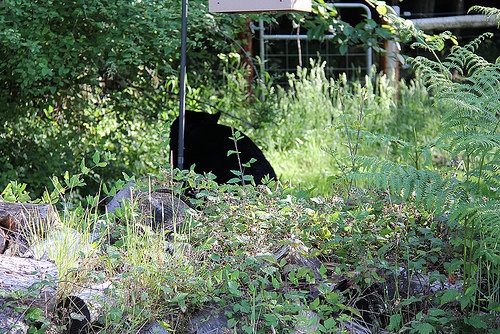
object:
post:
[382, 3, 498, 106]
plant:
[378, 34, 499, 181]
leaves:
[173, 205, 372, 317]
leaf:
[104, 96, 114, 105]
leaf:
[0, 0, 236, 218]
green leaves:
[0, 3, 235, 193]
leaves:
[273, 1, 425, 52]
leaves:
[176, 172, 424, 332]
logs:
[1, 256, 105, 309]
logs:
[1, 307, 52, 332]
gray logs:
[0, 254, 105, 321]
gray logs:
[1, 309, 59, 332]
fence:
[255, 5, 402, 89]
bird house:
[207, 0, 312, 14]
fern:
[408, 47, 498, 187]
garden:
[3, 80, 498, 330]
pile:
[0, 175, 482, 332]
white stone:
[98, 186, 196, 239]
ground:
[13, 190, 495, 329]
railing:
[372, 10, 499, 32]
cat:
[168, 109, 279, 186]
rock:
[265, 267, 309, 314]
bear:
[168, 110, 278, 187]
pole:
[178, 0, 188, 174]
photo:
[0, 0, 498, 334]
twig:
[265, 52, 420, 180]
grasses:
[299, 118, 407, 200]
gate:
[269, 33, 361, 71]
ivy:
[23, 180, 439, 321]